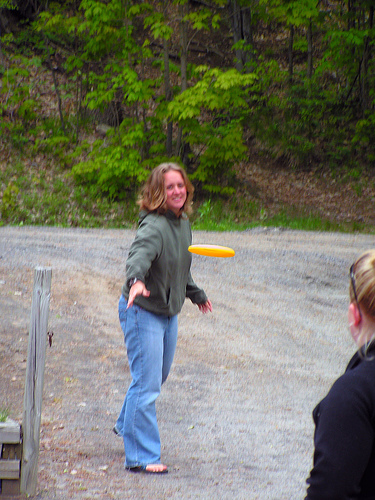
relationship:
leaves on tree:
[252, 79, 287, 134] [1, 0, 372, 206]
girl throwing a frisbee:
[112, 161, 212, 475] [186, 242, 235, 255]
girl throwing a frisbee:
[112, 161, 212, 475] [183, 231, 249, 265]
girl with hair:
[305, 249, 375, 500] [350, 252, 373, 313]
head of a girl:
[344, 254, 373, 352] [305, 249, 375, 500]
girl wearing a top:
[305, 249, 375, 500] [303, 341, 363, 498]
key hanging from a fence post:
[46, 329, 53, 346] [17, 267, 55, 497]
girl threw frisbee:
[112, 161, 212, 475] [185, 242, 236, 261]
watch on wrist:
[127, 276, 144, 288] [125, 275, 148, 286]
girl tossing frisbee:
[112, 161, 212, 475] [181, 220, 239, 264]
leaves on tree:
[164, 65, 260, 177] [32, 0, 270, 213]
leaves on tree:
[137, 78, 261, 148] [62, 45, 221, 138]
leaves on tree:
[38, 13, 194, 130] [71, 67, 155, 193]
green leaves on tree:
[106, 49, 131, 85] [126, 38, 203, 138]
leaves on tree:
[299, 18, 375, 155] [321, 43, 373, 114]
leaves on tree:
[164, 65, 260, 177] [154, 8, 186, 168]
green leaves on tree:
[0, 60, 45, 113] [3, 52, 43, 153]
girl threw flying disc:
[112, 161, 212, 475] [188, 244, 236, 257]